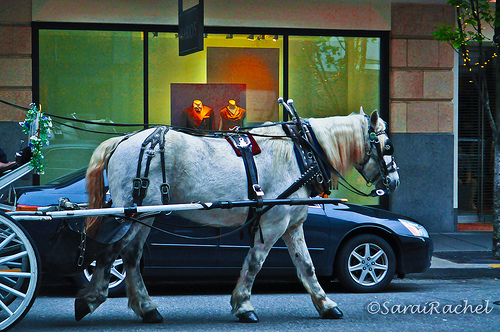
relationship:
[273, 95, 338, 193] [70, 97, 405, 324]
harness on horse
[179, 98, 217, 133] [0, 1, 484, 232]
mannequin in store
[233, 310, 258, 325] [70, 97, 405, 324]
hoof on a horse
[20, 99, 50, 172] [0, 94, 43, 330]
flowers on carriage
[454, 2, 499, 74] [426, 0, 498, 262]
christmas lights on tree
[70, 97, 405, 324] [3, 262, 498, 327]
horse on street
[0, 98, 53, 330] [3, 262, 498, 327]
carriage on street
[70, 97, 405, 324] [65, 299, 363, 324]
horse wearing black hooves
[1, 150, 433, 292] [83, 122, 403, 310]
car parked next to horse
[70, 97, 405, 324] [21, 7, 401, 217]
horse in front of storefront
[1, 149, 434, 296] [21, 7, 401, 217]
car in front of storefront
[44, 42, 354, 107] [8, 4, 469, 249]
wall inside store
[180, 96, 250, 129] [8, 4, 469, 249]
mannequins inside store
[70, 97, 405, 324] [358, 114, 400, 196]
horse with bridle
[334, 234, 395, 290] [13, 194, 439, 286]
wheel of car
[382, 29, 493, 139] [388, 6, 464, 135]
bricks of wall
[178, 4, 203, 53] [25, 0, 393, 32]
sign of roof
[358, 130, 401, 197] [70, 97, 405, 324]
bridle on horse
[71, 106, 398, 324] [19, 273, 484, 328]
horse on street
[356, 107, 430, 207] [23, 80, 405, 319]
head on horse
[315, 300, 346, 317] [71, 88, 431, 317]
hoof on horse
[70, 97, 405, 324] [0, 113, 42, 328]
horse pulling carriage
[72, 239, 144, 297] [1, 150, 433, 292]
wheel on car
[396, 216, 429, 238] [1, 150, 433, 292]
headlight on car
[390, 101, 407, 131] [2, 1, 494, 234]
stone on building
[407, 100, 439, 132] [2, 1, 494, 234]
stone on building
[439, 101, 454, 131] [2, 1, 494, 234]
stone on building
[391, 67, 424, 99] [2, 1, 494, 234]
stone on building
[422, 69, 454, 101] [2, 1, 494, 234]
brick on building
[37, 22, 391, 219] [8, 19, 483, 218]
window on storefront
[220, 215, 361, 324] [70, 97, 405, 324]
legs on horse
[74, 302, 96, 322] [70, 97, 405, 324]
black hooves on horse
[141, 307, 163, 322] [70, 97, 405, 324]
hoove on horse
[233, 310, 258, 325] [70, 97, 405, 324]
hoof on horse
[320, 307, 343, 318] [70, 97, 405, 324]
hoof on horse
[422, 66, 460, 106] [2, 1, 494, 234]
brick on building